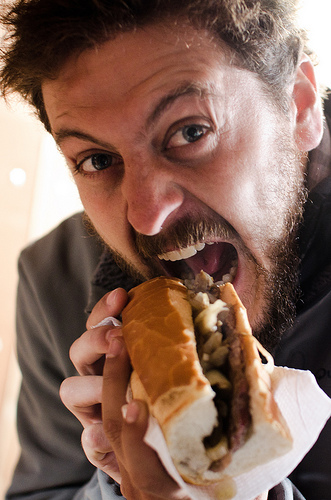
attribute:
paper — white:
[261, 368, 329, 460]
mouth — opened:
[156, 240, 239, 298]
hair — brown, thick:
[5, 15, 330, 91]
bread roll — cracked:
[124, 276, 203, 456]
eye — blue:
[165, 121, 212, 150]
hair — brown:
[1, 0, 330, 134]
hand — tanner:
[62, 288, 131, 493]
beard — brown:
[72, 172, 317, 360]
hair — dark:
[0, 3, 323, 122]